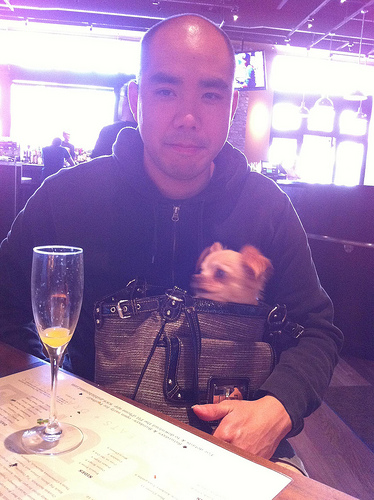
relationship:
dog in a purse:
[192, 241, 270, 307] [91, 290, 282, 431]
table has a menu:
[2, 453, 264, 500] [0, 403, 127, 500]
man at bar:
[41, 137, 72, 171] [1, 131, 42, 167]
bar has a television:
[1, 131, 42, 167] [234, 49, 267, 93]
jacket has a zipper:
[0, 132, 310, 243] [168, 205, 181, 278]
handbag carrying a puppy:
[91, 290, 282, 431] [192, 241, 270, 307]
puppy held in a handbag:
[192, 241, 270, 307] [91, 290, 282, 431]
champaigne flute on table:
[20, 245, 83, 455] [2, 453, 264, 500]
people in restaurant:
[91, 83, 128, 154] [2, 1, 374, 500]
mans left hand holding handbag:
[191, 390, 298, 465] [91, 290, 282, 431]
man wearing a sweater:
[0, 17, 344, 457] [0, 132, 310, 243]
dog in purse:
[192, 241, 270, 307] [91, 290, 282, 431]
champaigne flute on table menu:
[20, 245, 83, 455] [2, 453, 264, 500]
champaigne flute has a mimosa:
[26, 242, 86, 446] [43, 325, 70, 350]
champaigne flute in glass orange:
[20, 245, 83, 455] [37, 326, 73, 349]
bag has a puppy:
[91, 290, 282, 431] [192, 241, 270, 307]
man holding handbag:
[0, 17, 344, 457] [91, 290, 282, 431]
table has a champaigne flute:
[2, 453, 264, 500] [20, 245, 83, 455]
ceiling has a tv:
[236, 2, 373, 49] [234, 49, 267, 93]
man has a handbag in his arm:
[0, 17, 344, 457] [268, 192, 343, 466]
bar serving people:
[1, 131, 42, 167] [41, 137, 72, 171]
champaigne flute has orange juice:
[20, 245, 83, 455] [37, 326, 73, 349]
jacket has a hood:
[0, 132, 310, 243] [113, 126, 142, 163]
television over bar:
[234, 49, 267, 93] [1, 131, 42, 167]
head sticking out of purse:
[192, 241, 270, 307] [93, 285, 303, 446]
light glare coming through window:
[272, 48, 374, 185] [6, 72, 134, 162]